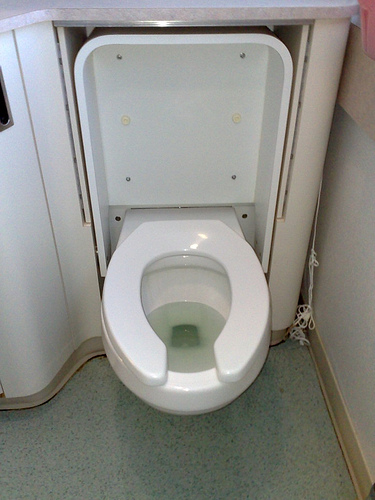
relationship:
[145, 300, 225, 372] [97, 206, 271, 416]
water in toilet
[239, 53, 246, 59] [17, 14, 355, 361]
bolt in wall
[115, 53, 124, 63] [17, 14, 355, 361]
bolt in wall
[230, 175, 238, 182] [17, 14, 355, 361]
bolt in wall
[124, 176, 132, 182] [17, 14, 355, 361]
bolt in wall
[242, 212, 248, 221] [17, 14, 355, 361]
bolt in wall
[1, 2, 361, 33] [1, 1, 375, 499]
countertop in bathroom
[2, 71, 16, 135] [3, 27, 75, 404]
hole in cabinet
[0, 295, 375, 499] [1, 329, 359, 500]
molding next to floor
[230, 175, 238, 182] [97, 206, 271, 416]
bolt above toilet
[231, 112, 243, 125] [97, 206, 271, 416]
screw above toilet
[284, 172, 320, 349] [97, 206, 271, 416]
cord next to toilet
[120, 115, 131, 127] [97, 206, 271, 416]
screw above toilet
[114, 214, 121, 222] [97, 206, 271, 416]
bolt above toilet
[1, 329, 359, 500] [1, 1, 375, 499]
floor of bathroom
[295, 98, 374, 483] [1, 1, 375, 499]
wall in bathroom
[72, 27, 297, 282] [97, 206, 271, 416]
toilet structure behind toilet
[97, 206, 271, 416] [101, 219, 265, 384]
toilet has toilet seat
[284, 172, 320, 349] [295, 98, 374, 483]
cord next to wall